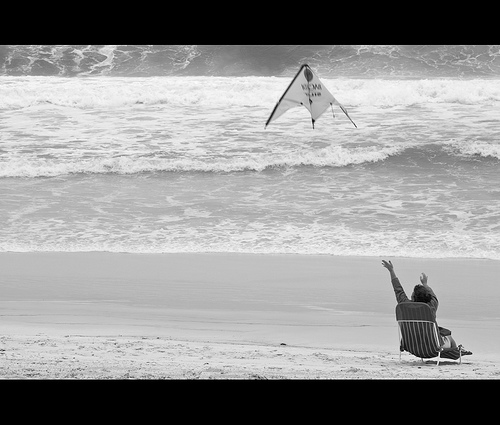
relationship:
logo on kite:
[302, 67, 320, 95] [263, 64, 357, 132]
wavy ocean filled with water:
[6, 48, 498, 337] [12, 46, 242, 256]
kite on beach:
[263, 64, 357, 130] [3, 42, 496, 379]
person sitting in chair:
[382, 259, 457, 348] [395, 302, 472, 367]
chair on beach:
[395, 302, 472, 367] [3, 42, 496, 379]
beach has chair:
[0, 250, 499, 380] [377, 300, 446, 375]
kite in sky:
[263, 64, 357, 130] [142, 48, 273, 109]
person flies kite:
[382, 259, 457, 348] [252, 52, 367, 134]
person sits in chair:
[382, 259, 457, 348] [394, 301, 473, 361]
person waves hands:
[382, 259, 457, 348] [345, 243, 450, 289]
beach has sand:
[0, 250, 499, 380] [2, 332, 497, 377]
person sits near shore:
[382, 259, 457, 348] [9, 232, 346, 306]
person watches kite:
[382, 259, 457, 348] [261, 61, 379, 173]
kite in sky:
[263, 64, 357, 130] [150, 52, 301, 92]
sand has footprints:
[0, 251, 499, 378] [0, 332, 499, 378]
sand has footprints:
[0, 334, 500, 380] [115, 332, 247, 379]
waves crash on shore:
[0, 137, 498, 178] [31, 221, 378, 307]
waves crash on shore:
[0, 45, 500, 178] [3, 279, 498, 384]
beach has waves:
[0, 250, 499, 380] [0, 135, 497, 183]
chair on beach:
[391, 300, 473, 367] [0, 250, 499, 380]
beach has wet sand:
[30, 253, 284, 367] [27, 259, 310, 299]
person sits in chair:
[360, 245, 458, 306] [389, 312, 473, 358]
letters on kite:
[299, 79, 326, 101] [263, 64, 357, 132]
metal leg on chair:
[399, 349, 462, 366] [391, 300, 473, 367]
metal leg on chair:
[419, 355, 427, 363] [391, 300, 473, 367]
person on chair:
[382, 259, 457, 348] [379, 301, 474, 364]